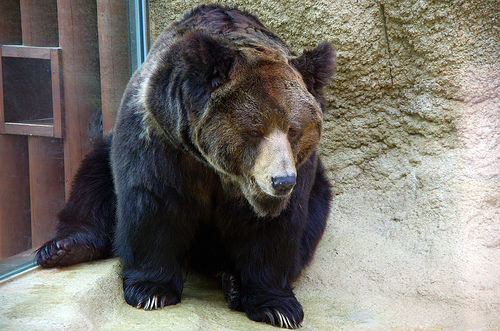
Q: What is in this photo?
A: A bear.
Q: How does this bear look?
A: Dangerous.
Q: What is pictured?
A: A bear.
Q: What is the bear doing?
A: Sitting.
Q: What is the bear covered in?
A: Fur.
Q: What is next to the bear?
A: Glass.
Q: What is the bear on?
A: A tan rock.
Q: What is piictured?
A: A large bear.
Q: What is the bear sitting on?
A: It's legs.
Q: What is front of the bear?
A: Its paws.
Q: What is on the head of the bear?
A: Brown fur.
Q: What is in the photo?
A: The bear.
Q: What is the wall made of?
A: Rock.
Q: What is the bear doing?
A: Sitting.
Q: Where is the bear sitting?
A: On the rocks.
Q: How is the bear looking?
A: Down.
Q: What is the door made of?
A: Wood.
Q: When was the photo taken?
A: Morning.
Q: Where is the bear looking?
A: To the right.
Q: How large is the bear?
A: Average size.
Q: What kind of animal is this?
A: Bear.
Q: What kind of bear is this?
A: Brown bear.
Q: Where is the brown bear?
A: Stone ground.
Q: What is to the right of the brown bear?
A: Stone wall.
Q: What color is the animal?
A: Brown.